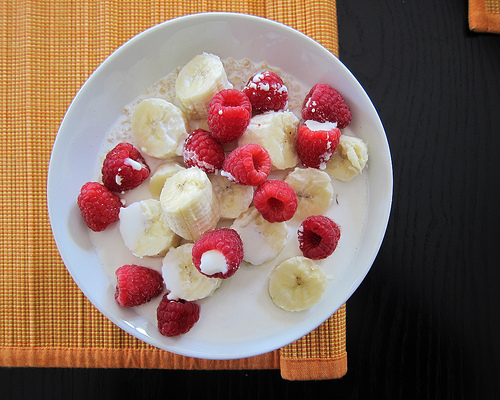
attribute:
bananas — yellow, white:
[138, 95, 213, 230]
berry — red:
[199, 95, 270, 188]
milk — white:
[96, 75, 332, 267]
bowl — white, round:
[56, 28, 382, 343]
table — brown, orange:
[3, 5, 349, 373]